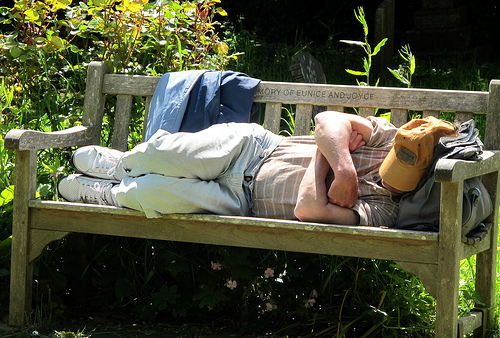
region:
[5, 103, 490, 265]
man sleeping on a bench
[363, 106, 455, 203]
yellow hat covering his face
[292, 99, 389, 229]
his arms are folded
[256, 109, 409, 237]
he is wearing a polo shirt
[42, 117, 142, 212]
he is wearing white sneakers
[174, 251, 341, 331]
flowers growing under the bench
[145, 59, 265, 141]
blue jacket hung over the bench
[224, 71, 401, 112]
writing on the bench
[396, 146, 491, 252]
brown duffel bag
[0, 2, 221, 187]
plants next to the bench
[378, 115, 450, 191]
a yellow baseball cap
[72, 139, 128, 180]
a man's white tennis shoe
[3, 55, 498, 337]
a gray wooden bench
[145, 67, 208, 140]
a pair of light blue jeans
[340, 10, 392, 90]
a long green leaf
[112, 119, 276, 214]
men's light pants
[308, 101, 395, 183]
the arm of a man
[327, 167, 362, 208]
the hand of a man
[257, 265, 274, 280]
a pink flower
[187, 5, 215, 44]
red and green flowers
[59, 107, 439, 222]
Man laying on a bench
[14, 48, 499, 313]
Lightly colored wooden bench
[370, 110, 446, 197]
Yellow baseball cap being worn by sleeping man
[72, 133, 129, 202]
Pair of white shoes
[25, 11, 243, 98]
Green shrubs standing behind bench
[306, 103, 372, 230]
Pair of pale arms crossed across a sleeping man's chest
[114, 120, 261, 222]
White pants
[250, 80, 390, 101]
A name carved into wooden bench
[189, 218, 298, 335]
Light colored flaws in the grass under a bench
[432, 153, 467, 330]
Wooden leg of a bench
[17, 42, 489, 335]
man sleeping on park bench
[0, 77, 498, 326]
brown park bench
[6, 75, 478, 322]
a park wooden bench with words on it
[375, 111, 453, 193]
a man wearing a yellow hat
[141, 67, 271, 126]
blue jacket draped over park bench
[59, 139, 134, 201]
a man wearing white tennis shoes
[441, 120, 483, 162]
a man using his scrugged up shirt as a pillow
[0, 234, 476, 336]
flowers growing underneath bench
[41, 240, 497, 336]
a bunch of grass under bench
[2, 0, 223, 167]
a rose bush next to park bench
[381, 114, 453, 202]
man wears yellow hat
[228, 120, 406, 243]
man wears brown shirt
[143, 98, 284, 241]
man wears white slacks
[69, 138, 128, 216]
man wears white shoes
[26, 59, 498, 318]
man sleeps on bench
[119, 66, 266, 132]
man has denim jacket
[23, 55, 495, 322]
bench is wooden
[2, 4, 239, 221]
bush behind bench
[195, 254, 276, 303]
pink flowers under bench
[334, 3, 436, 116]
tall thin green plant behind bench